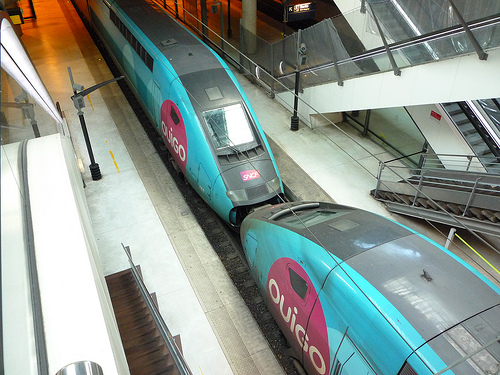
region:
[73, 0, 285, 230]
a light blue train engine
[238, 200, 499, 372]
a light blue train engine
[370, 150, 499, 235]
a metal staircase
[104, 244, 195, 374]
a metal staircase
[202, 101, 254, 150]
a train engine front windshield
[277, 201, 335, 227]
a train engine front windshield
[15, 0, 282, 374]
a train passenger boarding platform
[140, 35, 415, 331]
blue and black trains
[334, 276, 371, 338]
Blue color on the train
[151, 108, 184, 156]
Writings on the train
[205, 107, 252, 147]
Windscreen on the train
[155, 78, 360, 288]
Trains in the station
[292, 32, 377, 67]
Glass panes in the station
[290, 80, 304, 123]
Metallic pole in the photo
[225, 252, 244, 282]
black pebbles on the track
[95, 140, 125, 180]
yellow lines on the platform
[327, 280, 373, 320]
shiny blue paint on train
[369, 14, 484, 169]
long escalator in building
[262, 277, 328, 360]
white words on side of the train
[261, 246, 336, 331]
round pink symbol on side of train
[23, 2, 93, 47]
gold light reflecting on the platform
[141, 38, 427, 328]
pair of trains on the tracks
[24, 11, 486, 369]
Trains nose to nose in station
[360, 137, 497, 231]
stairwell with metal railings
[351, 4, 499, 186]
escalator with metal railings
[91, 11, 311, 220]
teal painted train car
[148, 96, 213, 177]
red circular train logo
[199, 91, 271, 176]
light blue train window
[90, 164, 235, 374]
white station flooring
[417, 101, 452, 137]
small red sign on escalator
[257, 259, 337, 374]
"ouigo" logo on train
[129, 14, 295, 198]
gray stripe on train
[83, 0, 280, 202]
this is a train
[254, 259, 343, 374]
writting on thee train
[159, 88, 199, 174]
writting on thee train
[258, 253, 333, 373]
this patch is pink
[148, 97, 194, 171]
this patch is pink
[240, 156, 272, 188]
this patch is pink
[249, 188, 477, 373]
the train is blue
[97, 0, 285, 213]
the train is blue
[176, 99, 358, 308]
2 trains touching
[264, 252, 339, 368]
ouigo ad on train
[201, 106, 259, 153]
windshield of a train